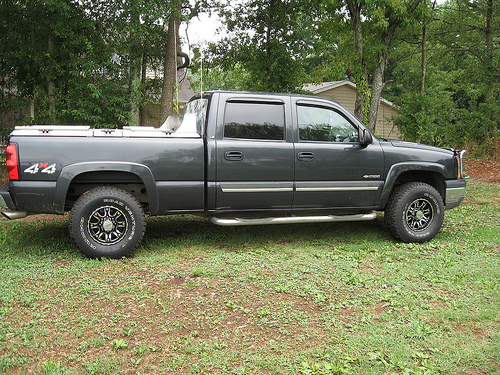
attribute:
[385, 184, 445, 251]
tire — newer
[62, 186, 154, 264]
tire — newer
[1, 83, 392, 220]
pickup — black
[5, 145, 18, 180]
light — red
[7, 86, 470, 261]
chevy — grey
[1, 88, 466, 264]
truck — grey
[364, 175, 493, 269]
wheel — silver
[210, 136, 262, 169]
handle — plastic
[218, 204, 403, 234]
board — silver